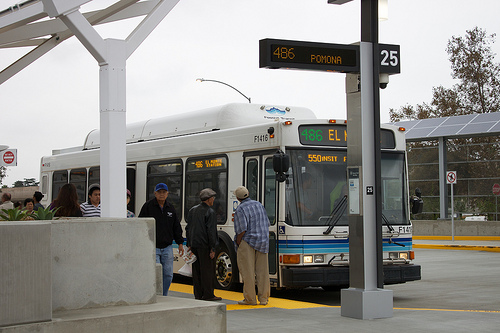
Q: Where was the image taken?
A: It was taken at the station.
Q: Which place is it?
A: It is a station.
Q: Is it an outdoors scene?
A: Yes, it is outdoors.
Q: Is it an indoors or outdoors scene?
A: It is outdoors.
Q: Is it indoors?
A: No, it is outdoors.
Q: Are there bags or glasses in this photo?
A: No, there are no glasses or bags.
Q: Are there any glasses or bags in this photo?
A: No, there are no glasses or bags.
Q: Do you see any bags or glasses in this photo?
A: No, there are no glasses or bags.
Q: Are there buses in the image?
A: Yes, there is a bus.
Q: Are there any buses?
A: Yes, there is a bus.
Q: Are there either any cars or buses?
A: Yes, there is a bus.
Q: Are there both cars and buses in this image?
A: No, there is a bus but no cars.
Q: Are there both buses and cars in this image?
A: No, there is a bus but no cars.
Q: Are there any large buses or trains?
A: Yes, there is a large bus.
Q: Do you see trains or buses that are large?
A: Yes, the bus is large.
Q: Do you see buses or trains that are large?
A: Yes, the bus is large.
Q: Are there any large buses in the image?
A: Yes, there is a large bus.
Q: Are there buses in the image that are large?
A: Yes, there is a bus that is large.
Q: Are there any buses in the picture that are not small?
A: Yes, there is a large bus.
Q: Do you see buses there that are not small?
A: Yes, there is a large bus.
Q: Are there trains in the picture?
A: No, there are no trains.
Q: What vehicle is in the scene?
A: The vehicle is a bus.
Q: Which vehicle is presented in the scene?
A: The vehicle is a bus.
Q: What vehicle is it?
A: The vehicle is a bus.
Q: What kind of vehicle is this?
A: This is a bus.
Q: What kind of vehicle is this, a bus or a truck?
A: This is a bus.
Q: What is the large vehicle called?
A: The vehicle is a bus.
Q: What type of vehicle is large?
A: The vehicle is a bus.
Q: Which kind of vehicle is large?
A: The vehicle is a bus.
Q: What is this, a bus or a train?
A: This is a bus.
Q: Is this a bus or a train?
A: This is a bus.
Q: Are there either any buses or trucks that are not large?
A: No, there is a bus but it is large.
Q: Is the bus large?
A: Yes, the bus is large.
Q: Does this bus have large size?
A: Yes, the bus is large.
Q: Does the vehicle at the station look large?
A: Yes, the bus is large.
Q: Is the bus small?
A: No, the bus is large.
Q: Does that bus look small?
A: No, the bus is large.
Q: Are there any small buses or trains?
A: No, there is a bus but it is large.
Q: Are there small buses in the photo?
A: No, there is a bus but it is large.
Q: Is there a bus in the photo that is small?
A: No, there is a bus but it is large.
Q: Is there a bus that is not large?
A: No, there is a bus but it is large.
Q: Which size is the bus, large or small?
A: The bus is large.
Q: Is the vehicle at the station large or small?
A: The bus is large.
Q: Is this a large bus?
A: Yes, this is a large bus.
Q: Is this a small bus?
A: No, this is a large bus.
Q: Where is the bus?
A: The bus is at the station.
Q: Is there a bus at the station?
A: Yes, there is a bus at the station.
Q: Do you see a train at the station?
A: No, there is a bus at the station.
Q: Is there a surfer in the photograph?
A: No, there are no surfers.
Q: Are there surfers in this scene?
A: No, there are no surfers.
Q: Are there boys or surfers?
A: No, there are no surfers or boys.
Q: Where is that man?
A: The man is on the sidewalk.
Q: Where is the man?
A: The man is on the sidewalk.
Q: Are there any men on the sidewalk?
A: Yes, there is a man on the sidewalk.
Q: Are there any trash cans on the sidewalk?
A: No, there is a man on the sidewalk.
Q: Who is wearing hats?
A: The man is wearing hats.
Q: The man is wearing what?
A: The man is wearing hats.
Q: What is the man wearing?
A: The man is wearing hats.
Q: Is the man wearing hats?
A: Yes, the man is wearing hats.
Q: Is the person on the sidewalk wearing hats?
A: Yes, the man is wearing hats.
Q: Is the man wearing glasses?
A: No, the man is wearing hats.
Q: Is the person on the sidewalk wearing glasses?
A: No, the man is wearing hats.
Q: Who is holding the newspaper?
A: The man is holding the newspaper.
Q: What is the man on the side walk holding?
A: The man is holding the newspaper.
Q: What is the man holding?
A: The man is holding the newspaper.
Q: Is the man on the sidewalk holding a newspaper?
A: Yes, the man is holding a newspaper.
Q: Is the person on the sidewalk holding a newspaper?
A: Yes, the man is holding a newspaper.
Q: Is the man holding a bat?
A: No, the man is holding a newspaper.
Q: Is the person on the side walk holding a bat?
A: No, the man is holding a newspaper.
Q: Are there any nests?
A: No, there are no nests.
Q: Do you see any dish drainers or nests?
A: No, there are no nests or dish drainers.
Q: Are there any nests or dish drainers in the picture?
A: No, there are no nests or dish drainers.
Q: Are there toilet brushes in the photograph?
A: No, there are no toilet brushes.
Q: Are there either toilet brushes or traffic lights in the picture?
A: No, there are no toilet brushes or traffic lights.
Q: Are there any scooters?
A: No, there are no scooters.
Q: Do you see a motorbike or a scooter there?
A: No, there are no scooters or motorcycles.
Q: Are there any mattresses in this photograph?
A: No, there are no mattresses.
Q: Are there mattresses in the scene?
A: No, there are no mattresses.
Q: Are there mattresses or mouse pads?
A: No, there are no mattresses or mouse pads.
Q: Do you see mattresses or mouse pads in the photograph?
A: No, there are no mattresses or mouse pads.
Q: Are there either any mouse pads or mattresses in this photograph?
A: No, there are no mattresses or mouse pads.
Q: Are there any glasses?
A: No, there are no glasses.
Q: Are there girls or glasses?
A: No, there are no glasses or girls.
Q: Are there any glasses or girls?
A: No, there are no glasses or girls.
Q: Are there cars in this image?
A: No, there are no cars.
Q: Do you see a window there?
A: Yes, there are windows.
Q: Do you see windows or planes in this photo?
A: Yes, there are windows.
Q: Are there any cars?
A: No, there are no cars.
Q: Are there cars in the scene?
A: No, there are no cars.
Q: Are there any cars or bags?
A: No, there are no cars or bags.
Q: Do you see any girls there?
A: No, there are no girls.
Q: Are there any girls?
A: No, there are no girls.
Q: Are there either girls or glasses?
A: No, there are no girls or glasses.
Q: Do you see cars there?
A: No, there are no cars.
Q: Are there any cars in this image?
A: No, there are no cars.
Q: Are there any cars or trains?
A: No, there are no cars or trains.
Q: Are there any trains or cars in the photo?
A: No, there are no cars or trains.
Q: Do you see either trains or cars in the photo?
A: No, there are no cars or trains.